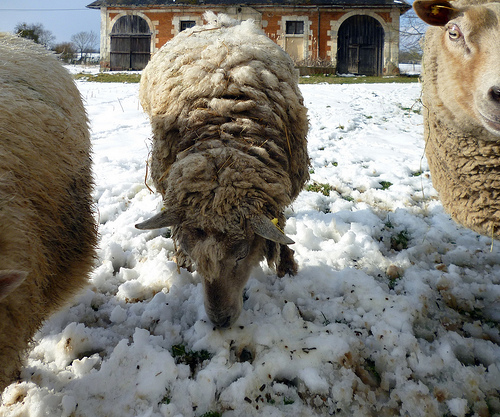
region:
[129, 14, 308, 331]
a sheep eating through the snow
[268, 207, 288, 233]
a yellow tag in a sheep ear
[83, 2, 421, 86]
a red brick and stone building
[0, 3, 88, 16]
a power line behind a building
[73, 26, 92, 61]
a bare leafless tree behind a house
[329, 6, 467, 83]
an arched doorway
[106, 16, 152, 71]
a wooden double door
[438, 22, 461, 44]
an eye of a sheep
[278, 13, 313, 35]
a window on a building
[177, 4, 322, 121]
shaggy wool on a sheep's back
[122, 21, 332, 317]
Fuzzy and dirty sheep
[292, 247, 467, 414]
The snow is dirty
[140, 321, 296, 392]
Sheep tracks in the snow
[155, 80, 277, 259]
The sheep fur is matted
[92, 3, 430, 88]
Brick building in background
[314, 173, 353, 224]
Grass poking through the snow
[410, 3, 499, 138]
The sheep is looking at the camera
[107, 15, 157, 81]
Door on front of building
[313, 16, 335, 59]
Brick sides on building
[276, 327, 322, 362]
Dirt on top of snow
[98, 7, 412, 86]
The house in the background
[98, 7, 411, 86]
The house is brown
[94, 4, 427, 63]
The house is made of brick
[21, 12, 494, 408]
Three sheep in the snow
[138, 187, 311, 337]
The sheep looking down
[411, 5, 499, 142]
The sheep looking straight ahead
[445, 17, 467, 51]
The eye of the sheep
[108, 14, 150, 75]
The old door of the house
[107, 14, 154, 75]
The door is made of wood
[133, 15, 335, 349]
Sheep eating snow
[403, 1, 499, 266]
One sheep looking at the camera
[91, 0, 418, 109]
Orange building behind sheep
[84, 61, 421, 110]
Grass in front of building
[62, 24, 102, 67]
Tree with no leaves beside building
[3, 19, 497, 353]
Three sheep standing in snow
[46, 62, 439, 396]
snow on the ground under sheep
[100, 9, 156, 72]
Brwon wooden doors on building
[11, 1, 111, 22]
Wire in sky going to building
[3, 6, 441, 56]
Sky is blue and cloudless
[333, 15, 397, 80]
The door of the old house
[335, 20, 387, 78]
The door is black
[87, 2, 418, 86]
The house is old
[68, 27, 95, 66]
The tree with no leaves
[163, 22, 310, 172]
The wool on the sheep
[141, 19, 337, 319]
The sheep is beige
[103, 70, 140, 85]
The green grass beside the snow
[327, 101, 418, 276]
The snow on the ground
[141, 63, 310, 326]
The head of the sheep in the snow